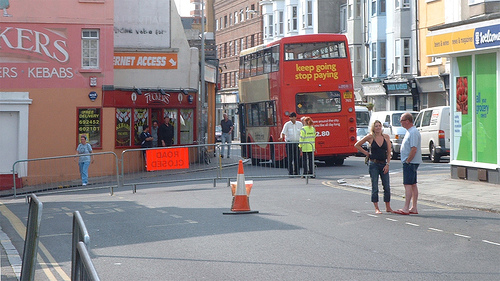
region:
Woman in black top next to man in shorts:
[354, 112, 430, 218]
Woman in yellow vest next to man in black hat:
[269, 103, 333, 188]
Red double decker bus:
[230, 25, 364, 170]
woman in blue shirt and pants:
[70, 128, 104, 195]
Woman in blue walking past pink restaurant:
[0, 2, 122, 184]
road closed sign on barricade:
[136, 136, 203, 193]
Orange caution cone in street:
[207, 151, 269, 234]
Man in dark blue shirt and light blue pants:
[213, 88, 240, 164]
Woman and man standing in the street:
[351, 98, 429, 227]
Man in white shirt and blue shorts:
[393, 98, 433, 222]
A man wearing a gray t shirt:
[393, 112, 425, 217]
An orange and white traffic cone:
[223, 158, 258, 214]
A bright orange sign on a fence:
[143, 145, 190, 170]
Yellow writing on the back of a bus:
[292, 62, 340, 81]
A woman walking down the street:
[71, 134, 95, 186]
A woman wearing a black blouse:
[352, 120, 396, 214]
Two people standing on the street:
[277, 112, 317, 177]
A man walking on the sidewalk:
[216, 110, 234, 159]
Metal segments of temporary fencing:
[11, 139, 316, 211]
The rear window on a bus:
[291, 90, 344, 115]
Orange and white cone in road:
[221, 157, 262, 222]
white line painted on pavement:
[440, 223, 477, 245]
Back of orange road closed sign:
[132, 142, 195, 175]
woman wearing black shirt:
[363, 131, 391, 167]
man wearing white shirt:
[392, 127, 430, 167]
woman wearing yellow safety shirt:
[293, 124, 318, 156]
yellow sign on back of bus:
[286, 60, 348, 86]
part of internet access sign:
[110, 50, 180, 71]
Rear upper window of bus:
[279, 38, 351, 64]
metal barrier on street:
[11, 188, 52, 263]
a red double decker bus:
[229, 28, 359, 168]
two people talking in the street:
[350, 110, 430, 215]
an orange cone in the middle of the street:
[226, 161, 258, 212]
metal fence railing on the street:
[8, 195, 105, 275]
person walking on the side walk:
[73, 128, 97, 187]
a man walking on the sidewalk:
[218, 108, 238, 157]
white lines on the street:
[343, 206, 499, 252]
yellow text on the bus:
[289, 63, 346, 81]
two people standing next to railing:
[278, 113, 318, 175]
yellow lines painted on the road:
[4, 202, 66, 280]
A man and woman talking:
[350, 113, 435, 221]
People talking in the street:
[352, 106, 433, 223]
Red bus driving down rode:
[231, 30, 368, 174]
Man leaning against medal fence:
[274, 105, 306, 180]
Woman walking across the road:
[68, 133, 100, 190]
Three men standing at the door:
[126, 108, 185, 160]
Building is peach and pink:
[1, 1, 116, 182]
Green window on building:
[445, 50, 499, 181]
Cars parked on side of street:
[357, 103, 454, 167]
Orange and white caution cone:
[226, 157, 258, 218]